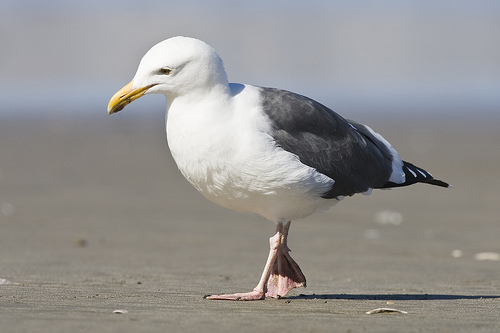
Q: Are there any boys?
A: No, there are no boys.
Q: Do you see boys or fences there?
A: No, there are no boys or fences.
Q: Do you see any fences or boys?
A: No, there are no boys or fences.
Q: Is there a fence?
A: No, there are no fences.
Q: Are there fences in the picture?
A: No, there are no fences.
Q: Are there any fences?
A: No, there are no fences.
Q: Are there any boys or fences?
A: No, there are no fences or boys.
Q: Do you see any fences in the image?
A: No, there are no fences.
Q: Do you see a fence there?
A: No, there are no fences.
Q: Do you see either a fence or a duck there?
A: No, there are no fences or ducks.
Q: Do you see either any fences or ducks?
A: No, there are no fences or ducks.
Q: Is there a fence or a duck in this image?
A: No, there are no fences or ducks.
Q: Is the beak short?
A: Yes, the beak is short.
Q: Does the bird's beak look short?
A: Yes, the beak is short.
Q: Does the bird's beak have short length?
A: Yes, the beak is short.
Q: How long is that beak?
A: The beak is short.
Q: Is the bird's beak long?
A: No, the beak is short.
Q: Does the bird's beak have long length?
A: No, the beak is short.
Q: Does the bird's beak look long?
A: No, the beak is short.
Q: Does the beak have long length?
A: No, the beak is short.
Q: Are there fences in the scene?
A: No, there are no fences.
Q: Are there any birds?
A: Yes, there is a bird.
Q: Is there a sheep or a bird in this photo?
A: Yes, there is a bird.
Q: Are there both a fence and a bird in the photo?
A: No, there is a bird but no fences.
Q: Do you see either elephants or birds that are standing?
A: Yes, the bird is standing.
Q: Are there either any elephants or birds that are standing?
A: Yes, the bird is standing.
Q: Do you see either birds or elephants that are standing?
A: Yes, the bird is standing.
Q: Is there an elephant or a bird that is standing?
A: Yes, the bird is standing.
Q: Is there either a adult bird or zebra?
A: Yes, there is an adult bird.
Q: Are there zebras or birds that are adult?
A: Yes, the bird is adult.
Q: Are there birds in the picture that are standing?
A: Yes, there is a bird that is standing.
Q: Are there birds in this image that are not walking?
A: Yes, there is a bird that is standing.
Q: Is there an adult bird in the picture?
A: Yes, there is an adult bird.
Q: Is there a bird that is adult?
A: Yes, there is a bird that is adult.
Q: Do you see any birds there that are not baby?
A: Yes, there is a adult bird.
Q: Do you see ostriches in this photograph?
A: No, there are no ostriches.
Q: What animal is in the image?
A: The animal is a bird.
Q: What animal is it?
A: The animal is a bird.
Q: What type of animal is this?
A: This is a bird.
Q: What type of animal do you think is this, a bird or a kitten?
A: This is a bird.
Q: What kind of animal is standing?
A: The animal is a bird.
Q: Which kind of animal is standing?
A: The animal is a bird.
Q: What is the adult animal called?
A: The animal is a bird.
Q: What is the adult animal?
A: The animal is a bird.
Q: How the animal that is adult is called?
A: The animal is a bird.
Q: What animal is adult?
A: The animal is a bird.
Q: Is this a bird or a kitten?
A: This is a bird.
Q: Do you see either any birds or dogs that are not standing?
A: No, there is a bird but it is standing.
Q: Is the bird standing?
A: Yes, the bird is standing.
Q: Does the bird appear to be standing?
A: Yes, the bird is standing.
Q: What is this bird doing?
A: The bird is standing.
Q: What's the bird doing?
A: The bird is standing.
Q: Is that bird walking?
A: No, the bird is standing.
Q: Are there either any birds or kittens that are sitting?
A: No, there is a bird but it is standing.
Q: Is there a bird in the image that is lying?
A: No, there is a bird but it is standing.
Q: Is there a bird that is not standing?
A: No, there is a bird but it is standing.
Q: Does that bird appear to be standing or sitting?
A: The bird is standing.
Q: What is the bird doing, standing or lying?
A: The bird is standing.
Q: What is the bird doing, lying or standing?
A: The bird is standing.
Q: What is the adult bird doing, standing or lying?
A: The bird is standing.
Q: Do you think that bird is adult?
A: Yes, the bird is adult.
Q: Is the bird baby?
A: No, the bird is adult.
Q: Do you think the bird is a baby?
A: No, the bird is adult.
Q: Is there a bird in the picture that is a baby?
A: No, there is a bird but it is adult.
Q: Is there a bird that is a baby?
A: No, there is a bird but it is adult.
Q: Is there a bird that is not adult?
A: No, there is a bird but it is adult.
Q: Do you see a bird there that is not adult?
A: No, there is a bird but it is adult.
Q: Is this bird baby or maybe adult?
A: The bird is adult.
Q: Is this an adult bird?
A: Yes, this is an adult bird.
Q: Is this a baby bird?
A: No, this is an adult bird.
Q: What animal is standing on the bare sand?
A: The animal is a bird.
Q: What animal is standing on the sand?
A: The animal is a bird.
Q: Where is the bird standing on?
A: The bird is standing on the sand.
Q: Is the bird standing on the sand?
A: Yes, the bird is standing on the sand.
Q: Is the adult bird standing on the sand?
A: Yes, the bird is standing on the sand.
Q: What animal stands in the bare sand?
A: The bird stands in the sand.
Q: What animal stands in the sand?
A: The bird stands in the sand.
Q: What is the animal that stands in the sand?
A: The animal is a bird.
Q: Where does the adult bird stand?
A: The bird stands in the sand.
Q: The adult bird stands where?
A: The bird stands in the sand.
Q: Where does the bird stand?
A: The bird stands in the sand.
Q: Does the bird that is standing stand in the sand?
A: Yes, the bird stands in the sand.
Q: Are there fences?
A: No, there are no fences.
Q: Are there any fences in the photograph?
A: No, there are no fences.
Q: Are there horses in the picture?
A: No, there are no horses.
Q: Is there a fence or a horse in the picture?
A: No, there are no horses or fences.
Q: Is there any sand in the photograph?
A: Yes, there is sand.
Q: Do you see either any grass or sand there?
A: Yes, there is sand.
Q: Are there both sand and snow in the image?
A: No, there is sand but no snow.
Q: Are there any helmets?
A: No, there are no helmets.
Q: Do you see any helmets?
A: No, there are no helmets.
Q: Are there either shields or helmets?
A: No, there are no helmets or shields.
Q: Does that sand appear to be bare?
A: Yes, the sand is bare.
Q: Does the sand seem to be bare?
A: Yes, the sand is bare.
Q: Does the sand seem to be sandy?
A: No, the sand is bare.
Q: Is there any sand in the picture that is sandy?
A: No, there is sand but it is bare.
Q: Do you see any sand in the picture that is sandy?
A: No, there is sand but it is bare.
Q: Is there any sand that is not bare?
A: No, there is sand but it is bare.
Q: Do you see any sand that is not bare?
A: No, there is sand but it is bare.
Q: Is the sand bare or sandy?
A: The sand is bare.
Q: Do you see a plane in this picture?
A: No, there are no airplanes.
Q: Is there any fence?
A: No, there are no fences.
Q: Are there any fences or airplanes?
A: No, there are no fences or airplanes.